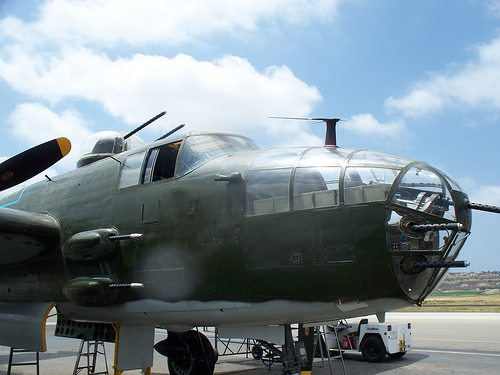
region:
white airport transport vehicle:
[275, 294, 441, 370]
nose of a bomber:
[352, 136, 477, 329]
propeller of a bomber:
[0, 109, 77, 209]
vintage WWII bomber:
[19, 77, 456, 372]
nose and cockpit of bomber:
[85, 89, 480, 317]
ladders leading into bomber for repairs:
[0, 294, 139, 371]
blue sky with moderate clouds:
[1, 3, 497, 289]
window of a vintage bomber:
[105, 134, 201, 201]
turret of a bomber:
[73, 94, 198, 182]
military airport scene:
[3, 30, 484, 364]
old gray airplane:
[12, 109, 456, 344]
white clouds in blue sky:
[5, 16, 56, 60]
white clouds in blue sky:
[31, 55, 73, 89]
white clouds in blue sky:
[97, 8, 151, 70]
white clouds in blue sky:
[165, 35, 245, 89]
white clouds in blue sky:
[237, 5, 312, 72]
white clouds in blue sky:
[240, 58, 302, 106]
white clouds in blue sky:
[407, 38, 495, 88]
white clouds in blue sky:
[375, 75, 439, 136]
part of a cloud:
[246, 80, 285, 127]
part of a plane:
[297, 233, 337, 290]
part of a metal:
[431, 247, 451, 280]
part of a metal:
[124, 277, 149, 322]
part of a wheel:
[194, 347, 202, 362]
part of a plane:
[302, 213, 323, 236]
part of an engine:
[83, 283, 103, 307]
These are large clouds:
[46, 26, 220, 157]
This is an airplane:
[77, 109, 397, 306]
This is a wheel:
[131, 330, 182, 363]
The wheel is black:
[163, 316, 223, 373]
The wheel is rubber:
[154, 329, 184, 364]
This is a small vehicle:
[314, 323, 448, 368]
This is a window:
[129, 142, 214, 184]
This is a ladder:
[47, 323, 110, 368]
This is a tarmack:
[424, 298, 496, 362]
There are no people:
[217, 336, 297, 372]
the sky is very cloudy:
[0, 1, 499, 270]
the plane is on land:
[0, 110, 471, 365]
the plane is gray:
[11, 117, 467, 374]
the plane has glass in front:
[178, 131, 463, 307]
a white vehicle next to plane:
[331, 321, 409, 354]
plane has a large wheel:
[163, 329, 216, 374]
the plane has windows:
[118, 142, 183, 187]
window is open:
[140, 135, 183, 182]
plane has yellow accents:
[39, 135, 121, 370]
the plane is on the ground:
[6, 124, 473, 347]